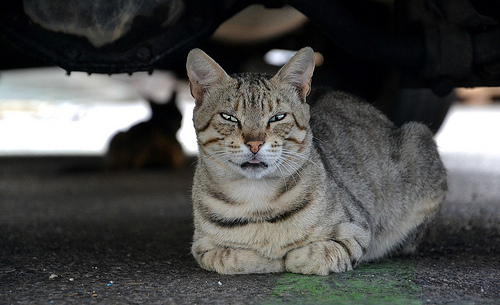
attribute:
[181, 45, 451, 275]
cat — big, brown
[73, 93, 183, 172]
cat — outlined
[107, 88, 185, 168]
cat — under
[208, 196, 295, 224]
fur — light gray, cat's fur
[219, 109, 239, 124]
eye — slitted , thin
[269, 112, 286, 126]
eye — slitted , thin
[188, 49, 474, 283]
cat — big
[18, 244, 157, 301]
asphalt — lightly littered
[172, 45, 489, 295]
cat — gray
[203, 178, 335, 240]
stripes — black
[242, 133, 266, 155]
nose — pink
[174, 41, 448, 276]
nose — pink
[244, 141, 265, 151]
nose — pink, cat's nose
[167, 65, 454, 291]
cat — brown, big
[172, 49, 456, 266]
cat — under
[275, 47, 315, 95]
ear — brown, big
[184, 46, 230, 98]
ear — brown, big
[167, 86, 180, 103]
ear — big, brown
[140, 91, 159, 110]
ear — big, brown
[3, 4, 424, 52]
undercarriage — indistinct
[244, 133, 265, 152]
nose — brown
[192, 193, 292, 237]
stripes — quarter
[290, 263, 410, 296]
asphalt — stained green